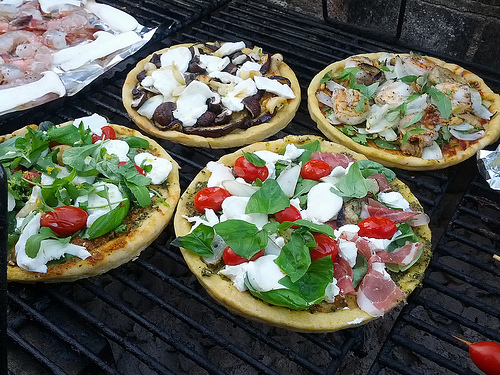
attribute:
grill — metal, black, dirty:
[1, 1, 499, 373]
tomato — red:
[195, 186, 231, 210]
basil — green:
[216, 218, 276, 259]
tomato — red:
[235, 156, 269, 183]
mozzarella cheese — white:
[304, 180, 344, 222]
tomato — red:
[356, 216, 397, 239]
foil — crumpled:
[477, 143, 500, 190]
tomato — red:
[302, 159, 330, 180]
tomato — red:
[275, 203, 301, 226]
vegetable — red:
[455, 330, 499, 374]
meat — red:
[334, 229, 418, 317]